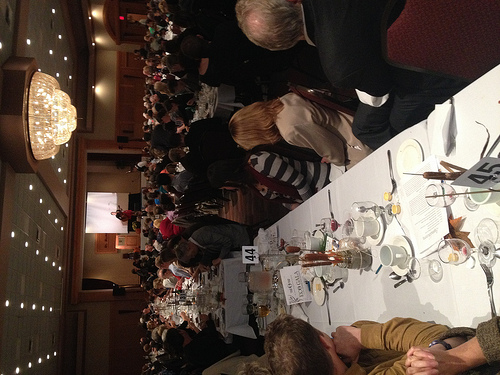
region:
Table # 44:
[239, 242, 260, 269]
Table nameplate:
[274, 264, 317, 305]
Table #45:
[448, 153, 498, 192]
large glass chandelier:
[28, 68, 80, 164]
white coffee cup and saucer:
[375, 234, 415, 276]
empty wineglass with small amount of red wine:
[432, 234, 494, 266]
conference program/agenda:
[388, 153, 455, 256]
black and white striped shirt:
[239, 152, 325, 206]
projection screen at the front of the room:
[80, 189, 135, 235]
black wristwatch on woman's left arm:
[424, 337, 454, 351]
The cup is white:
[373, 238, 409, 273]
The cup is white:
[343, 217, 376, 242]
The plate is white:
[388, 134, 428, 183]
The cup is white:
[294, 231, 324, 258]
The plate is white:
[306, 274, 328, 311]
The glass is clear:
[433, 233, 495, 270]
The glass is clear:
[398, 257, 440, 285]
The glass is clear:
[410, 181, 461, 214]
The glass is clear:
[309, 213, 350, 238]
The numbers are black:
[235, 243, 260, 268]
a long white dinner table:
[195, 222, 497, 330]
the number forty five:
[451, 158, 498, 199]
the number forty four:
[231, 238, 269, 280]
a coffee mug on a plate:
[377, 232, 412, 270]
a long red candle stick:
[408, 165, 460, 195]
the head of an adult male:
[252, 319, 342, 370]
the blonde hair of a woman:
[221, 106, 276, 147]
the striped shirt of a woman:
[217, 141, 299, 202]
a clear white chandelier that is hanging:
[10, 81, 90, 152]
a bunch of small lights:
[0, 216, 68, 293]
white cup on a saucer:
[378, 233, 415, 277]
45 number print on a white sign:
[448, 155, 499, 194]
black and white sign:
[277, 263, 315, 306]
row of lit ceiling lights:
[17, 180, 67, 233]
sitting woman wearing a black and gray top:
[205, 145, 330, 205]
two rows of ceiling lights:
[0, 296, 55, 371]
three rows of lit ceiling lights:
[1, 226, 61, 372]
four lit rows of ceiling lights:
[1, 182, 66, 373]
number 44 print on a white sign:
[239, 245, 261, 264]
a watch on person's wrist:
[426, 334, 454, 351]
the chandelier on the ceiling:
[0, 66, 97, 173]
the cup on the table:
[365, 235, 421, 279]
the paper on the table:
[380, 154, 466, 260]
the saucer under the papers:
[388, 130, 422, 168]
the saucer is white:
[391, 138, 428, 173]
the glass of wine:
[316, 203, 355, 239]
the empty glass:
[339, 191, 383, 227]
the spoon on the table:
[386, 275, 428, 287]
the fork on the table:
[473, 249, 499, 316]